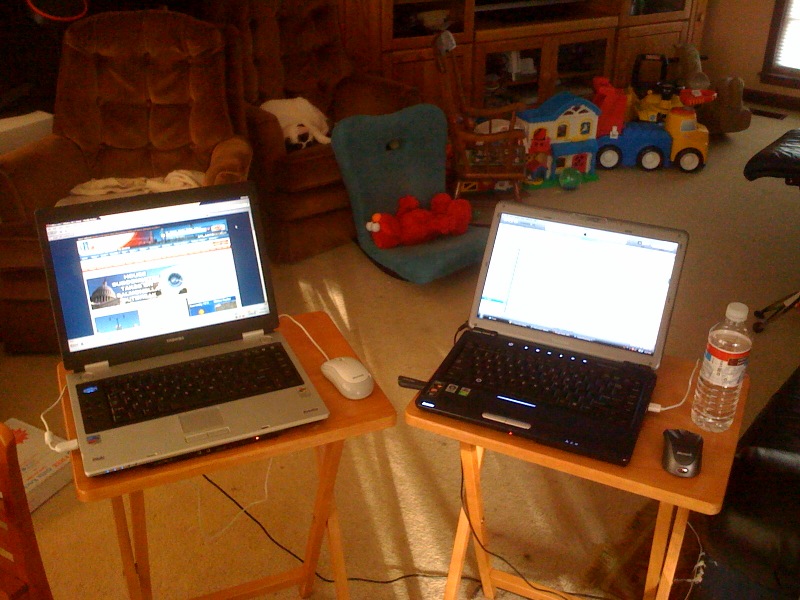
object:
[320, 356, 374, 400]
mouse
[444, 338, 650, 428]
keyboard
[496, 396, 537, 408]
light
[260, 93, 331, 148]
cat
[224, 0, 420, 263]
chair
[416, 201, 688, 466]
laptop